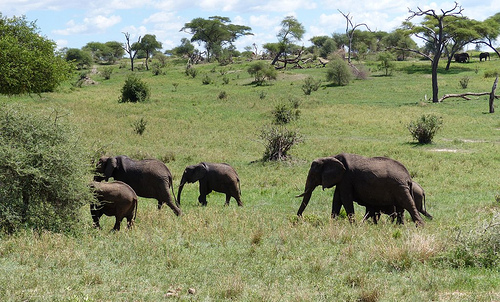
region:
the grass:
[213, 250, 311, 300]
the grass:
[320, 234, 355, 294]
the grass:
[322, 276, 331, 296]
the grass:
[333, 290, 342, 295]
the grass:
[311, 271, 336, 298]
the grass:
[291, 234, 321, 287]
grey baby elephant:
[178, 150, 250, 214]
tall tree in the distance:
[176, 14, 256, 64]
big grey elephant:
[272, 142, 422, 238]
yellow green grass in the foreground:
[4, 231, 499, 299]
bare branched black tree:
[396, 1, 468, 112]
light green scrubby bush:
[0, 96, 102, 241]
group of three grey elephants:
[60, 137, 245, 227]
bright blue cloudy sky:
[1, 1, 498, 58]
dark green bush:
[110, 71, 165, 115]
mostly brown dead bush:
[247, 127, 306, 174]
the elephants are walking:
[60, 127, 445, 241]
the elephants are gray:
[65, 130, 425, 270]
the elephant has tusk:
[282, 175, 337, 217]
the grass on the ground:
[180, 203, 373, 293]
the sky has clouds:
[75, 10, 291, 69]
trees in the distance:
[127, 32, 472, 116]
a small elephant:
[170, 159, 277, 232]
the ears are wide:
[310, 136, 362, 207]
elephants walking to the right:
[95, 115, 272, 231]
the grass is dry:
[368, 232, 473, 266]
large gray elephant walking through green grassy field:
[290, 147, 431, 238]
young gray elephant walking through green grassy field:
[167, 155, 252, 205]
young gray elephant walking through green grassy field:
[65, 176, 140, 231]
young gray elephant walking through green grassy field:
[355, 172, 431, 222]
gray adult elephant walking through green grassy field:
[83, 149, 186, 223]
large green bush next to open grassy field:
[0, 9, 81, 100]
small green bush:
[114, 69, 152, 106]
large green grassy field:
[1, 48, 498, 300]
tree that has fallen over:
[263, 43, 335, 74]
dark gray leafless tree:
[379, 1, 471, 106]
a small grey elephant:
[171, 156, 240, 210]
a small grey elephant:
[77, 172, 137, 230]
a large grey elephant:
[91, 149, 184, 213]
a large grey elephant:
[292, 147, 424, 232]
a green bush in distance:
[119, 73, 152, 105]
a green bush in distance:
[402, 112, 447, 150]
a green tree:
[5, 109, 90, 231]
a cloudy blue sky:
[0, 0, 497, 57]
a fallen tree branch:
[433, 84, 497, 102]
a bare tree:
[117, 29, 144, 72]